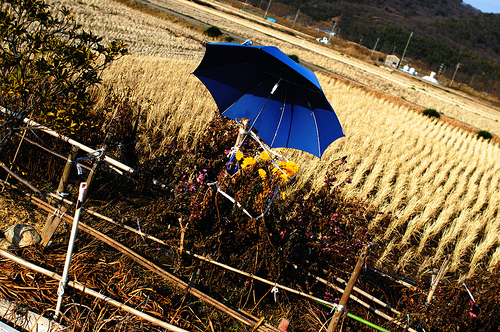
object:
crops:
[368, 129, 462, 189]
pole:
[205, 115, 256, 222]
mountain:
[346, 0, 498, 101]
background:
[0, 0, 499, 108]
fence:
[0, 104, 426, 331]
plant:
[0, 0, 141, 154]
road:
[138, 1, 500, 147]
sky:
[458, 0, 497, 22]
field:
[0, 0, 500, 295]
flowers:
[222, 138, 317, 206]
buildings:
[309, 22, 341, 34]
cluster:
[377, 46, 449, 86]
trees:
[447, 52, 498, 92]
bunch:
[188, 153, 280, 225]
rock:
[0, 217, 48, 255]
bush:
[198, 19, 228, 45]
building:
[257, 12, 282, 26]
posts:
[44, 176, 97, 326]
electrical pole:
[393, 29, 420, 74]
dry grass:
[0, 186, 239, 332]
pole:
[311, 250, 378, 330]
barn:
[381, 51, 405, 72]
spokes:
[189, 40, 349, 159]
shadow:
[7, 221, 27, 251]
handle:
[225, 128, 255, 162]